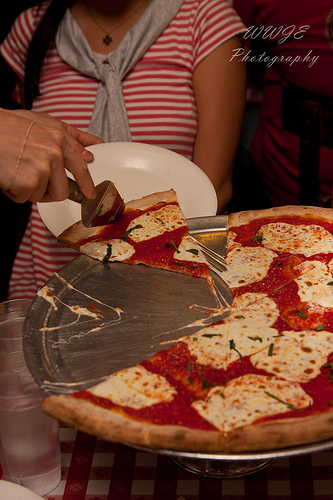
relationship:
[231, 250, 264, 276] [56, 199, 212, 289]
cheese on pizza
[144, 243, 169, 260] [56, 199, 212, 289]
sauce on pizza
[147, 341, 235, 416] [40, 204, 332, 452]
sauce on pizza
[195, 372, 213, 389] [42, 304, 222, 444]
flake on a pizza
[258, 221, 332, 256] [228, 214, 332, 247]
cheese and sauce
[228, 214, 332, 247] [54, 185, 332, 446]
sauce on pizza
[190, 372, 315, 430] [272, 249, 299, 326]
cheese on red sauce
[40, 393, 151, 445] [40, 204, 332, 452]
crust on pizza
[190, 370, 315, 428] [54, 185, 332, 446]
cheese on pizza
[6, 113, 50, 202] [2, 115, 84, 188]
band on hand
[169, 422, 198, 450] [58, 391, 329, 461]
spot on crust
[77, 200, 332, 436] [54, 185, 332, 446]
sauce on pizza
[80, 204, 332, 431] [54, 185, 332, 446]
cheese on pizza